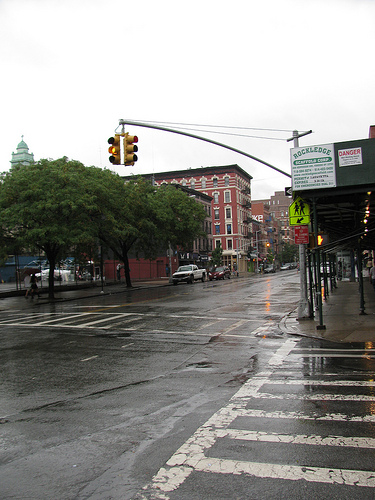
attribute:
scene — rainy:
[0, 9, 373, 499]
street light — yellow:
[107, 132, 123, 168]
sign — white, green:
[289, 141, 338, 193]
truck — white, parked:
[169, 264, 209, 288]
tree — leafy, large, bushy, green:
[2, 153, 127, 304]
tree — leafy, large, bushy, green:
[83, 174, 151, 293]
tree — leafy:
[136, 183, 207, 286]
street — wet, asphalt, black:
[4, 265, 374, 499]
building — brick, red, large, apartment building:
[77, 162, 255, 284]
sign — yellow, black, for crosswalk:
[288, 194, 313, 227]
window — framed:
[221, 187, 233, 203]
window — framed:
[223, 203, 234, 221]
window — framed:
[223, 220, 234, 236]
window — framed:
[225, 236, 235, 254]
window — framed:
[212, 234, 224, 255]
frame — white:
[223, 186, 233, 206]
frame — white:
[223, 203, 234, 220]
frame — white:
[223, 220, 233, 238]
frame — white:
[224, 235, 235, 251]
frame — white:
[212, 238, 224, 255]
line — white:
[265, 376, 374, 391]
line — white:
[239, 408, 374, 426]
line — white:
[219, 427, 374, 452]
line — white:
[194, 456, 374, 488]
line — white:
[144, 334, 298, 498]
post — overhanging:
[115, 117, 296, 185]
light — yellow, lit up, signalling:
[104, 144, 121, 156]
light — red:
[124, 134, 139, 145]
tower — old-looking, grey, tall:
[8, 132, 36, 177]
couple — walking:
[21, 270, 43, 302]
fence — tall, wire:
[0, 253, 108, 301]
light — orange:
[263, 240, 273, 250]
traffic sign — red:
[292, 224, 312, 247]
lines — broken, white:
[78, 338, 149, 368]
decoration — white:
[149, 173, 250, 195]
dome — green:
[16, 140, 30, 152]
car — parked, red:
[206, 262, 233, 282]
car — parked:
[262, 262, 278, 276]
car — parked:
[280, 259, 300, 273]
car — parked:
[317, 261, 334, 276]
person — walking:
[163, 262, 172, 283]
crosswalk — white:
[2, 305, 289, 342]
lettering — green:
[291, 146, 336, 191]